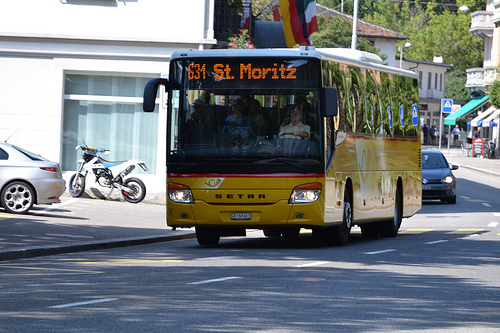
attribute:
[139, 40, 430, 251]
bus — yellow, black, red, driving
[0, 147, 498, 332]
road — paved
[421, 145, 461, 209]
car — silver, volkswagon, grey, driving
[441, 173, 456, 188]
headlight — on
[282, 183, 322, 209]
headlight — on, large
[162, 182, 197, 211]
headlight — on, large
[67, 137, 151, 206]
motorcycle — parked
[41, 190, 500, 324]
line — white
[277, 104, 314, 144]
bus driver — steering, driving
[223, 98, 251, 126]
passenger — sitting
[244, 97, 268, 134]
passenger — sitting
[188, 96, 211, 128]
passenger — sitting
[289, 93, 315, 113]
passenger — sitting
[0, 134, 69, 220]
car — parked, gray, silver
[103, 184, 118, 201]
kickstand — silver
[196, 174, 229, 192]
decal — french horn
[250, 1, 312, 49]
flag — yellow, red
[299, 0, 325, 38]
flag — green, red, white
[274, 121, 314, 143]
shirt — yellow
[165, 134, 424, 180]
stripe — red